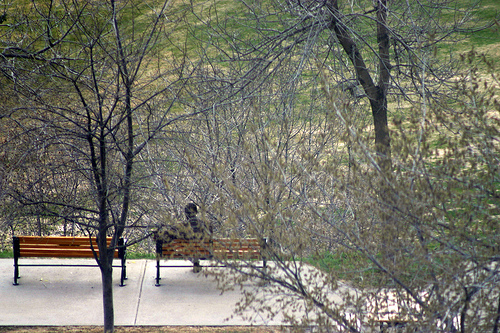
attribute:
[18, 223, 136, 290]
bench — tan, wooden, wood, brown, metal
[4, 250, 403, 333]
sidewalk — white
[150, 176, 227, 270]
man — sitting, wearing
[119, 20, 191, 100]
leaves — dead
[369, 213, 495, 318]
plant — steep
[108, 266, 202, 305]
cement — steps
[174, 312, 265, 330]
bridge — wooden